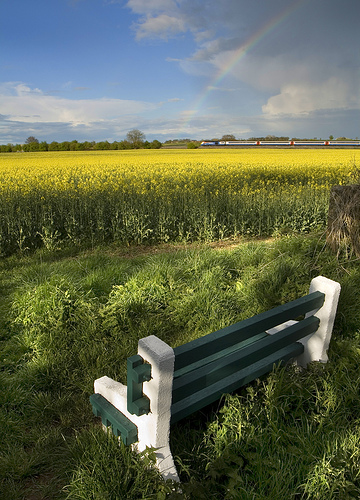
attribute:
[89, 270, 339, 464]
bench — green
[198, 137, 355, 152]
train — long, passing by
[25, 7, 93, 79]
sky — clear, blue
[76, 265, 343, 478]
bench — green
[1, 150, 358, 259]
grass — green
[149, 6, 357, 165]
rainbow — big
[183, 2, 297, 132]
rainbow — big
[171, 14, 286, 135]
rainbow — big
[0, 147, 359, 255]
flowers — Tall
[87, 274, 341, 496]
bench — green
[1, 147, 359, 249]
grass — green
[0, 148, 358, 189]
flowers — yellow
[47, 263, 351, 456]
bench — green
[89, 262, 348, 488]
bench — long, blue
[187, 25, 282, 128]
rainbow — big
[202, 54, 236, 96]
rainbow — big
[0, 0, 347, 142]
sky — clear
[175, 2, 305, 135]
rainbow — big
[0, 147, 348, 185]
flowers — yellow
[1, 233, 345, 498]
grass — green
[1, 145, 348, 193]
flowers — yellow